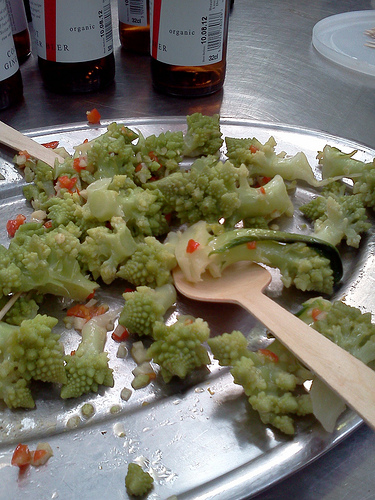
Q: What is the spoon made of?
A: Wood.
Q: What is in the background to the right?
A: A plastic lid.